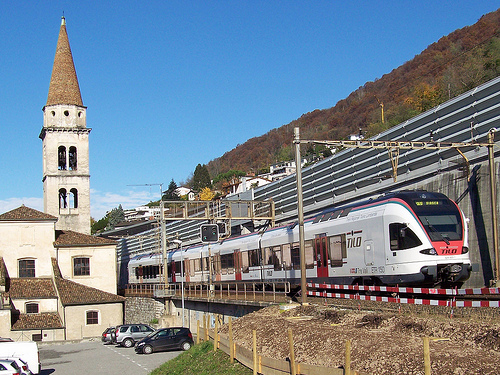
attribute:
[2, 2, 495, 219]
sky — blue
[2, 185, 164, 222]
clouds — white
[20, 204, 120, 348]
wall — tan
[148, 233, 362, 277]
windows — passenger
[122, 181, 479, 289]
train — white , red 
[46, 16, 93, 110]
steeple — brown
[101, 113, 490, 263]
lines — white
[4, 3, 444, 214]
sky — blue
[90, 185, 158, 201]
clouds — little bit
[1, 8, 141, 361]
building — white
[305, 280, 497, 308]
notice — red, white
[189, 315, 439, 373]
posts — brown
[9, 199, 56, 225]
roof — brown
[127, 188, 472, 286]
train — white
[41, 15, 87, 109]
steeple — brown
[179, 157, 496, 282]
train — black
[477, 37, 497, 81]
tree — green, brown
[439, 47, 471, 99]
tree — green, brown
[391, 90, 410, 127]
tree — green, brown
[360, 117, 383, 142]
tree — green, brown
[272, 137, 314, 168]
tree — green, brown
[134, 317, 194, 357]
car — black